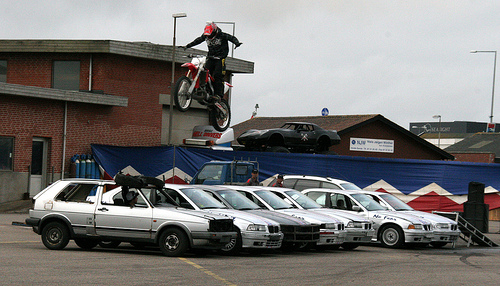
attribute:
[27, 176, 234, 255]
car — parked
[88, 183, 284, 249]
car — parked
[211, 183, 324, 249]
car — parked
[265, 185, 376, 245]
car — parked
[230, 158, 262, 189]
guard — security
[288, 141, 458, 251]
cars — white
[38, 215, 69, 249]
tire — rear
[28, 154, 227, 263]
car — parked, silver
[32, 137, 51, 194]
door — closed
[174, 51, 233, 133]
bike — red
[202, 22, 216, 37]
helmet — motorcross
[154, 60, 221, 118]
bike — red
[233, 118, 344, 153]
car — black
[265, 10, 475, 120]
sky — cloudy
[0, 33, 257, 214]
house — brown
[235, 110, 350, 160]
car — parked, black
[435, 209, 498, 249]
stunt ramp — small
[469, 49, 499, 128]
pole — light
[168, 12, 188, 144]
pole — light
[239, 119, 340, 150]
corvette — black , classic 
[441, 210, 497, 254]
ramp — small, black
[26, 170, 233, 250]
silver car — parked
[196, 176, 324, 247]
car — black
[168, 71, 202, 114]
wheel — black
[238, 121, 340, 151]
car — black